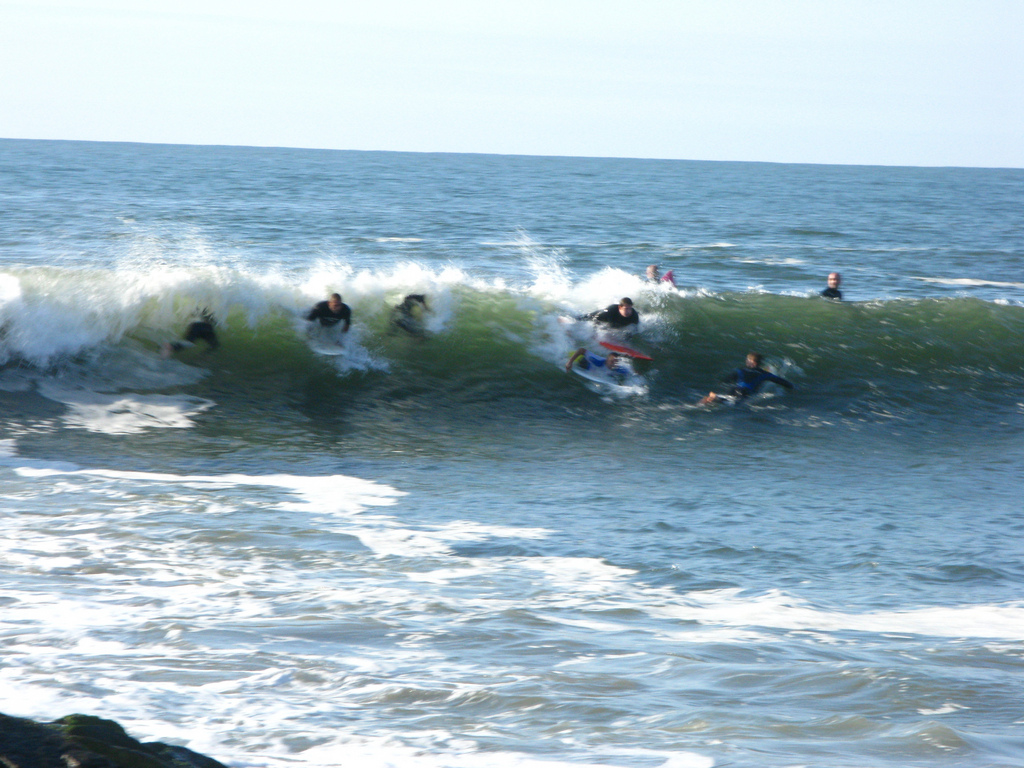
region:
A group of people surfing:
[153, 212, 856, 435]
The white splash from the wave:
[26, 253, 413, 307]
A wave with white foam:
[18, 251, 1020, 410]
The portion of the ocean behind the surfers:
[8, 136, 1017, 324]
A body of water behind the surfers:
[8, 142, 1002, 292]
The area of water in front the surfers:
[28, 418, 1015, 763]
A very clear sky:
[1, 13, 1022, 172]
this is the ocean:
[32, 136, 991, 677]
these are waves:
[146, 449, 704, 764]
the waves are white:
[108, 487, 450, 715]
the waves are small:
[93, 233, 672, 464]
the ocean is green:
[345, 268, 903, 581]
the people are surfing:
[239, 271, 666, 431]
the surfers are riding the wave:
[117, 253, 839, 560]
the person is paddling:
[550, 285, 740, 413]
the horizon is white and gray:
[213, 119, 581, 256]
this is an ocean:
[52, 154, 833, 651]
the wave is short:
[184, 250, 643, 446]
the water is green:
[128, 411, 376, 729]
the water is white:
[81, 467, 344, 756]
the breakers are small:
[84, 221, 470, 756]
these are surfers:
[105, 198, 772, 467]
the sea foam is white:
[125, 233, 370, 355]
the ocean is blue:
[260, 127, 546, 249]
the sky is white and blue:
[333, 51, 555, 144]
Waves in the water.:
[50, 209, 828, 476]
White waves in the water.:
[136, 377, 912, 736]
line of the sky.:
[272, 115, 996, 287]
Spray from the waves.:
[92, 169, 513, 373]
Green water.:
[389, 248, 978, 501]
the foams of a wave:
[396, 246, 486, 305]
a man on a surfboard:
[295, 279, 366, 357]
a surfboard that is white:
[301, 328, 352, 368]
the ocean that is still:
[676, 435, 874, 581]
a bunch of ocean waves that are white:
[354, 556, 517, 684]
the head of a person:
[604, 299, 642, 316]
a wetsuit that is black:
[721, 364, 776, 403]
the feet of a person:
[698, 385, 728, 415]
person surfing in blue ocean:
[266, 256, 368, 358]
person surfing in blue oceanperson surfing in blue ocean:
[356, 274, 473, 370]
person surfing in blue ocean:
[567, 268, 689, 396]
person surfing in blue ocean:
[708, 338, 801, 437]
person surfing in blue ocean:
[614, 239, 713, 309]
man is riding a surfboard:
[567, 296, 654, 360]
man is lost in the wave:
[156, 302, 224, 356]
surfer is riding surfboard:
[299, 286, 353, 354]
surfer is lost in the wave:
[384, 277, 445, 336]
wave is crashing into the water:
[1, 223, 1019, 402]